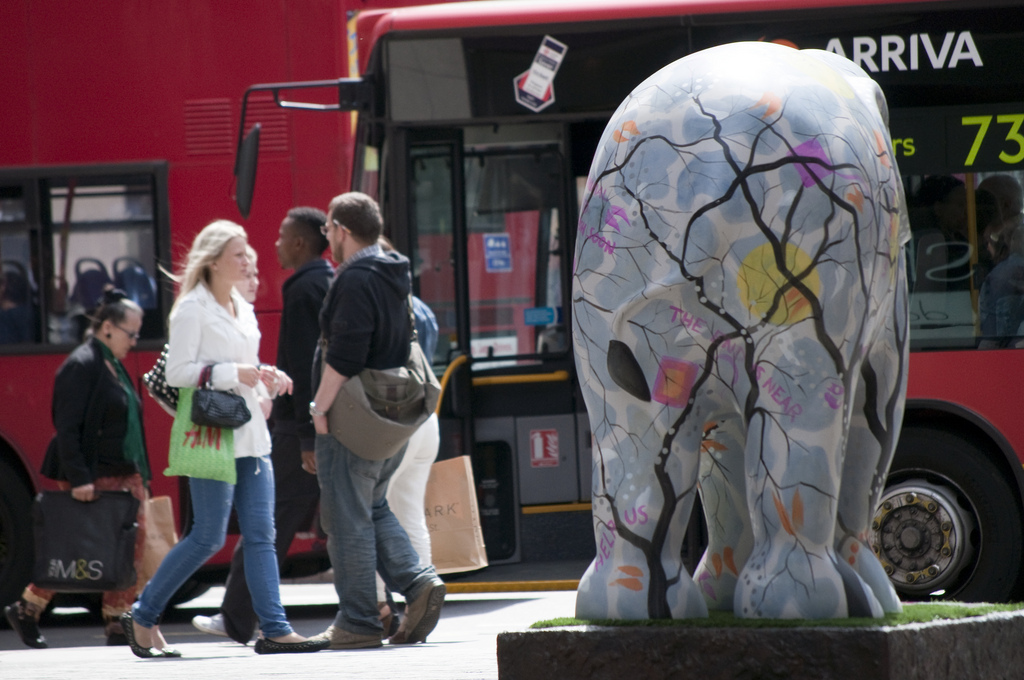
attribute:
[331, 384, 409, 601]
pants — grey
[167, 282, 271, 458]
jacket — white